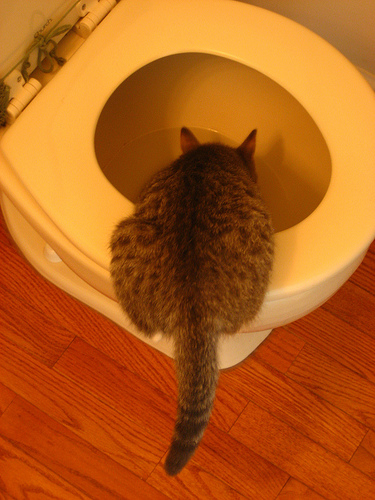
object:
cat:
[109, 126, 273, 476]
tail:
[163, 321, 219, 478]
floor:
[1, 207, 375, 500]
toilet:
[0, 0, 374, 376]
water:
[113, 125, 245, 207]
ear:
[180, 125, 202, 154]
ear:
[236, 128, 258, 159]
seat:
[0, 0, 374, 305]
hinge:
[4, 68, 42, 127]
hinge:
[74, 0, 118, 40]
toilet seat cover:
[1, 1, 78, 80]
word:
[34, 18, 52, 37]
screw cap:
[4, 69, 27, 100]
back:
[109, 162, 277, 340]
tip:
[163, 447, 196, 476]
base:
[0, 187, 273, 371]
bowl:
[94, 52, 332, 235]